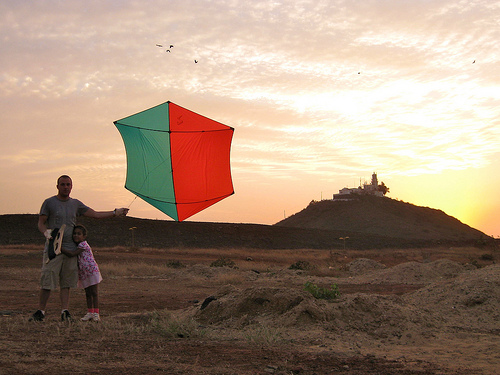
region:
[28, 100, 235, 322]
a man holding a kite with a girl on his side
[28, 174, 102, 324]
a little girl hugging the guy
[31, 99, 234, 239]
a man holding a kite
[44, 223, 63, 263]
hold of string the guy is holding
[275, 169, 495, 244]
a hill with building top of it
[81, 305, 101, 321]
shoes and pink socks the girl is wearing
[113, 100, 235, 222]
a kite the guy is holding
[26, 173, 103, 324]
a guy and a little girl standing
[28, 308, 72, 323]
shoes and socks the guy is wearing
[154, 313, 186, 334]
a patch of brown grass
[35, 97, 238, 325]
man and child flying kite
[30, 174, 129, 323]
girl is hugging a man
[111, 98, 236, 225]
large green and red kite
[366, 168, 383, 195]
lighthouse on a hill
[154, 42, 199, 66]
birds are flying in the sky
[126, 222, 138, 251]
pole in field with lights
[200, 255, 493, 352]
mounds of dirt in field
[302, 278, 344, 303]
weeds growing in dirt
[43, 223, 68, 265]
spool of string for kite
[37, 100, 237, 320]
man is holding kite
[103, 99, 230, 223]
red and green kite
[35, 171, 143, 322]
man holding red and green kite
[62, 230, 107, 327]
girl hugging the man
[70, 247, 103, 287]
pink out of little girl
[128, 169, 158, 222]
string of red and green kite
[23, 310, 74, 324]
black shoes of man with kite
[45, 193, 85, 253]
gray shirt of man with kite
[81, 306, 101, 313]
pink socks of girl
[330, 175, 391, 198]
house on the hill in the distance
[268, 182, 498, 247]
sun setting behind hill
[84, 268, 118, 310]
part of a knee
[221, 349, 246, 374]
part of a grounmd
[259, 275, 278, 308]
aprt of a hill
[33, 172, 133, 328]
This is a person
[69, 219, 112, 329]
This is a child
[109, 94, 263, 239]
This is a kite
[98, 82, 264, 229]
A green and yellow kite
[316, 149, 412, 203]
House on a hill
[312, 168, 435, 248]
House on a hill